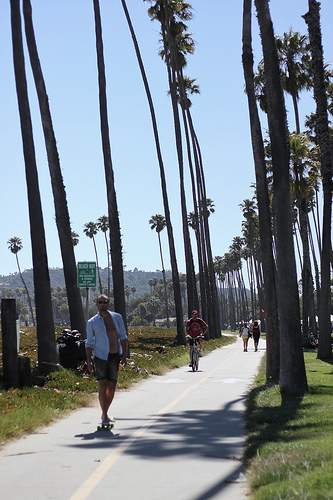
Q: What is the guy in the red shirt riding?
A: Bike.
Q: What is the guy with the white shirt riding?
A: Skateboard.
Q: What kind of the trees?
A: Palm.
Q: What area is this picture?
A: Park.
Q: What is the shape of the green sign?
A: Rectangle.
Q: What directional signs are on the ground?
A: Arrows.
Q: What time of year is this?
A: Summer.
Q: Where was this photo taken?
A: On a sidewalk.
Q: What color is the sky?
A: Blue.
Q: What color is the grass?
A: Green.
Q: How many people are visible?
A: Four.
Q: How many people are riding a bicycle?
A: One.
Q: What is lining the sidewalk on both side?
A: Palm trees.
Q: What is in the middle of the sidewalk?
A: A solid yellow line.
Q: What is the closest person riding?
A: A skateboard.